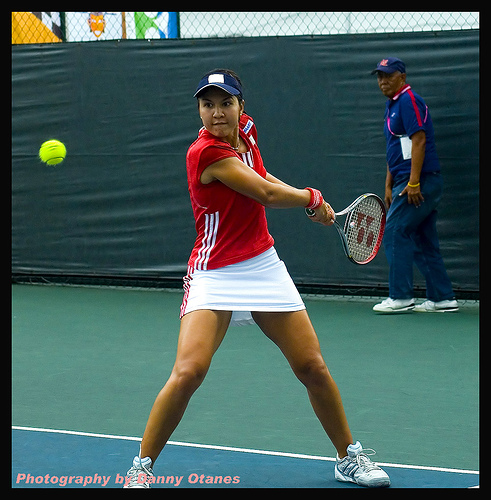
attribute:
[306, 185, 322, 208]
wristband — red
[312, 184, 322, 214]
wristband — red, white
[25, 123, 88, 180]
ball — yellow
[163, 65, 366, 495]
woman — playing tennis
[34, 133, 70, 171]
ball — neon, yellow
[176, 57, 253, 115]
visor — blue, white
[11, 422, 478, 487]
markings — white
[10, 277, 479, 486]
tennis court — green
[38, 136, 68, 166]
tennis ball — small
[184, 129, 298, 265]
shirt — Adidas, red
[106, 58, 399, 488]
woman — hitting a backhand, playing tennis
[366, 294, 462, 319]
shoes — white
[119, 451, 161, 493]
shoes — white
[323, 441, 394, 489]
shoes — white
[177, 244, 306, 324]
tennis skirt — white, Adidas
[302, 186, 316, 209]
wristband — red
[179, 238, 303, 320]
skirt — white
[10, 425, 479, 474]
line — white